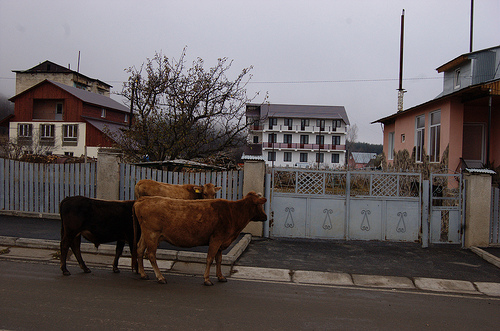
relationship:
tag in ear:
[189, 185, 219, 196] [188, 184, 208, 198]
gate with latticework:
[266, 165, 466, 245] [293, 167, 325, 197]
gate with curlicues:
[266, 165, 466, 245] [426, 174, 461, 206]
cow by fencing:
[131, 175, 218, 200] [1, 152, 465, 248]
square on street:
[231, 265, 290, 281] [1, 245, 498, 327]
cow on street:
[127, 191, 272, 285] [0, 259, 497, 329]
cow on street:
[57, 195, 142, 276] [1, 258, 499, 330]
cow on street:
[53, 192, 143, 279] [5, 253, 499, 330]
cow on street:
[127, 191, 272, 285] [5, 253, 499, 330]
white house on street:
[242, 96, 354, 171] [17, 250, 353, 328]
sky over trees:
[2, 0, 499, 147] [118, 51, 259, 175]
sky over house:
[2, 0, 499, 147] [9, 57, 147, 154]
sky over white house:
[2, 0, 499, 147] [241, 102, 350, 170]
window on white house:
[299, 151, 314, 167] [241, 102, 350, 170]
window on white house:
[336, 136, 341, 146] [241, 102, 350, 170]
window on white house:
[326, 149, 340, 165] [241, 102, 350, 170]